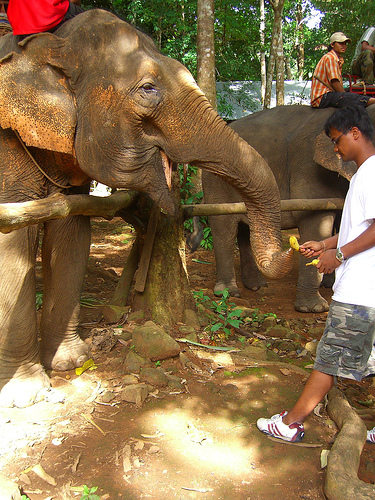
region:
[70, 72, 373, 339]
man is feeding the elephant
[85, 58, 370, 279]
man is feeding the elephant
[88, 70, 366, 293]
man is feeding the elephant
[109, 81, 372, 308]
man is feeding the elephant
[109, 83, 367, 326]
man is feeding the elephant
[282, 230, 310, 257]
this is a banana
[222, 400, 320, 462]
this is a white sneaker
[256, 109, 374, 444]
this is a man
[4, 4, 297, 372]
this is an elephant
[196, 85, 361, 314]
this is an elephant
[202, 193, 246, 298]
the foot of an elephant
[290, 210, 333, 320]
the foot of an elephant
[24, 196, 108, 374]
the foot of an elephant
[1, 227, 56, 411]
the foot of an elephant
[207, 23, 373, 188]
man sitting on the elephant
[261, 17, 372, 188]
man sitting on the elephant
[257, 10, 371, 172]
man sitting on the elephant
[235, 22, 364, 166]
man sitting on the elephant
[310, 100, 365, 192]
boy is wearing eyeglasses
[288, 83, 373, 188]
boy is wearing eyeglasses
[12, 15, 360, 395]
this is a elephant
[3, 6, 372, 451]
man is feeding an elephant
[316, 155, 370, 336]
man wearing a white shirt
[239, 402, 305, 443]
man wearing white shoes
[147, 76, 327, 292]
elephants trunk is curved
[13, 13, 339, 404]
the elephant is brown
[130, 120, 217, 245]
elephant has mouth open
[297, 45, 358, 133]
man wearing plaid shirt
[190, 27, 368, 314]
man sitting on an elephant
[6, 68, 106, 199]
orange tips on elephant ear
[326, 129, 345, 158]
a man wearing glasses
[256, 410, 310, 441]
a man wearing a white and red shoe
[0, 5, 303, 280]
a elephant eating a banana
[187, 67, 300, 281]
a long elephant trunk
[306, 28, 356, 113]
a man sitting on a elephant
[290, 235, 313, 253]
a man holding a banana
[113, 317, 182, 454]
several rocks on the ground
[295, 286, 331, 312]
a elephant's foot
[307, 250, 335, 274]
a man holding a banana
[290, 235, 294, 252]
FOOD IN THE HAND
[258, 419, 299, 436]
BOY WEARING TENNIS SHOES